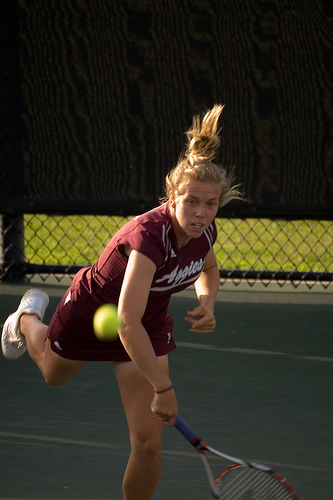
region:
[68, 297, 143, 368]
Tennis ball in the air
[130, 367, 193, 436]
hair tie on woman's wrist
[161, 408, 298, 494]
Blue handled tennis racket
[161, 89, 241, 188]
pony tail flying up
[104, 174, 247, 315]
woman in maroon tennis shirt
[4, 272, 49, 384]
bright white tennis shoe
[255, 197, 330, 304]
grass through a chain link fence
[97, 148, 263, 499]
woman playing tennis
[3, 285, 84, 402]
leg lifted in air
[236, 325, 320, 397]
line on a tennis court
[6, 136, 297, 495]
blonde female tennis player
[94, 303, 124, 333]
round neon green tennis ball flying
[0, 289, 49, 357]
dirty white tennis shoe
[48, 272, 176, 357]
tight maroon tennis skirt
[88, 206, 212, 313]
tight maroon tennis shirt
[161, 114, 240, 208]
blond hair tied in a loose bun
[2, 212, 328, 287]
metal chain link fence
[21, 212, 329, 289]
greenish yellow cut grass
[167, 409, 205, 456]
blue wrapped metal handle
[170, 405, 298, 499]
blue orange and white tennis racket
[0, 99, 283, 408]
Girl playing tennis in Aggies uniform.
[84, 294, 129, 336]
Tennis ball flying in the air.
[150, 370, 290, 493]
Tennis racket being held by girl.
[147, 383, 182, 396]
Black bracelet on tennis player's wrist.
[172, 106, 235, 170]
Ponytail of girl playing tennis.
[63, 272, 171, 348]
Skirt of Aggies uniform worn by tennis player.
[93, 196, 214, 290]
Shirt portion of uniform worn by tennis player.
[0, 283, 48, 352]
White sneaker worn by tennis player.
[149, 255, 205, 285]
Name of school on tennis player's uniform.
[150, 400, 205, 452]
Handle of tennis racket held by girl.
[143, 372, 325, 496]
holding tennis racket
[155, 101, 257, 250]
girl with blonde hair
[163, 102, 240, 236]
blonde hair standing straight up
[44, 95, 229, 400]
woman wearing burgundy tennis dress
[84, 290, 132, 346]
yellow tennis ball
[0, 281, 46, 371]
white tennis shoes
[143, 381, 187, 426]
brown bracelet on wrist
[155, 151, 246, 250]
woman with grimace on her face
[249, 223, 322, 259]
green grass behind fence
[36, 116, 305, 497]
woman hitting tennis ball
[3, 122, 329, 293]
fence behind woman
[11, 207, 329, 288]
grassy area visible through fence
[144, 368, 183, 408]
dark band on woman's right wrist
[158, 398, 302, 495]
woman holding tennis racket with her right hand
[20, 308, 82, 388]
woman's right leg is elevated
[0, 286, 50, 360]
woman is wearing a white shoe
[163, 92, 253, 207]
woman has blond hair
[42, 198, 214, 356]
woman is wearing maroon tennis outfit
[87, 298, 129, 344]
tennis ball appears to be in motion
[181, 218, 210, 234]
woman's mouth is open